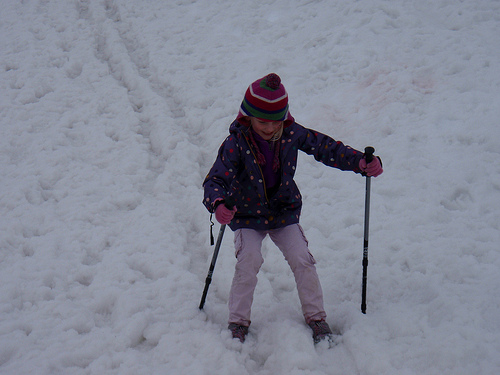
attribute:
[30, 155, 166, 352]
snow — full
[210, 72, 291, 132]
hat — red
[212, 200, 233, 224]
gloves — pink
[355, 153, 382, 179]
gloves — pink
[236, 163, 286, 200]
jacket — warm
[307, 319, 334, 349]
shoe — black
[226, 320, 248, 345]
shoe — black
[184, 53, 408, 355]
kid — skiing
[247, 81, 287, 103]
stripe — white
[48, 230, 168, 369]
snow — white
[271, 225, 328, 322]
leg — apart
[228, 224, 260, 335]
leg — apart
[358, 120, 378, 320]
pole — thin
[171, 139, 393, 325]
poles — black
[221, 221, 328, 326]
pants — pink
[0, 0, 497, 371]
snow — white, heavy, full